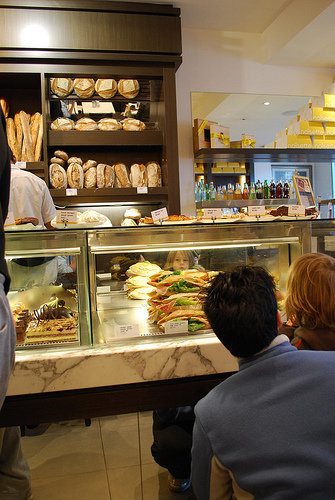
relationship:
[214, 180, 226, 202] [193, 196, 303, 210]
bottle on counter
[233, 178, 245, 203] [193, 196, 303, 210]
bottle on counter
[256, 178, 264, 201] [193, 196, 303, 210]
bottle on counter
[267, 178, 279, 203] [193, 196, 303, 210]
bottle on counter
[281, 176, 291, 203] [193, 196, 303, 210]
bottle on counter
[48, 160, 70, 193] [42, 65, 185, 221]
bread loaves on display shelf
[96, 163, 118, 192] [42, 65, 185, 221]
bread loaves on display shelf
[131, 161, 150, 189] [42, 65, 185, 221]
bread loaves on display shelf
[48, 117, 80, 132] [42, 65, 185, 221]
bread loaves on display shelf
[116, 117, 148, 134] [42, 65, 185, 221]
bread loaves on display shelf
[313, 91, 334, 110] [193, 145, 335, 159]
boxes on shelf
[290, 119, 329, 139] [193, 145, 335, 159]
boxes on shelf